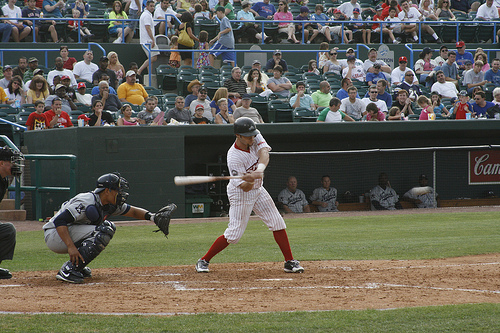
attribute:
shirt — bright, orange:
[116, 83, 149, 105]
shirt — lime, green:
[309, 90, 337, 112]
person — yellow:
[104, 0, 130, 29]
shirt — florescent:
[106, 10, 130, 28]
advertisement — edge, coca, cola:
[466, 144, 498, 184]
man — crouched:
[40, 170, 163, 283]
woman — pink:
[270, 0, 298, 31]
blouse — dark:
[270, 13, 293, 24]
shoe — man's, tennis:
[282, 258, 302, 276]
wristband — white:
[251, 157, 266, 184]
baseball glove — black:
[153, 206, 184, 258]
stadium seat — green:
[274, 98, 284, 114]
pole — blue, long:
[285, 43, 302, 66]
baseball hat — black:
[229, 114, 264, 146]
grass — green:
[418, 232, 427, 252]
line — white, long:
[328, 271, 354, 305]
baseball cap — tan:
[121, 70, 136, 79]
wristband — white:
[252, 160, 285, 214]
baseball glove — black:
[144, 203, 187, 228]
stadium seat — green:
[275, 100, 286, 120]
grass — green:
[429, 315, 440, 327]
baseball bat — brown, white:
[184, 172, 204, 195]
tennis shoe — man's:
[53, 261, 93, 284]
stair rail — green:
[48, 153, 74, 186]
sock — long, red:
[273, 240, 308, 287]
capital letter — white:
[475, 162, 484, 172]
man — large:
[119, 78, 129, 96]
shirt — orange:
[124, 80, 144, 99]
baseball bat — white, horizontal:
[187, 176, 247, 206]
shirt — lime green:
[314, 90, 329, 105]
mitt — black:
[139, 169, 202, 269]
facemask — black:
[92, 173, 159, 213]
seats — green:
[146, 33, 416, 109]